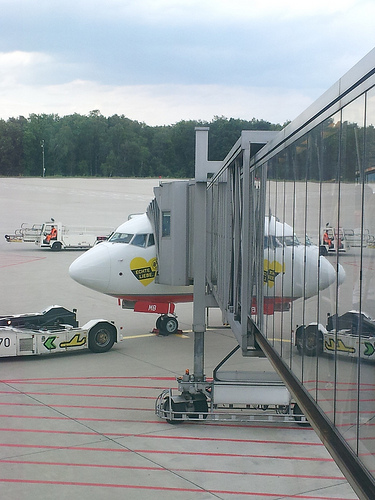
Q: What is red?
A: Lines.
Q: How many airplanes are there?
A: One.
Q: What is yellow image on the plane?
A: Heart.